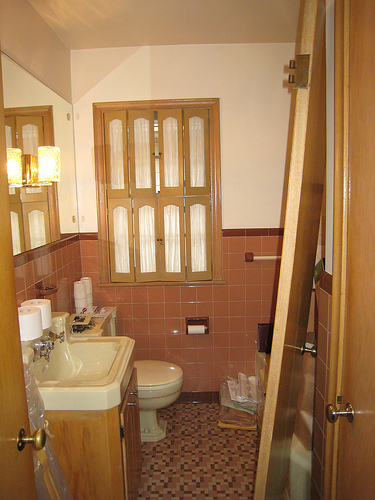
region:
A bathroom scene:
[7, 11, 361, 488]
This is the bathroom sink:
[21, 313, 137, 410]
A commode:
[132, 339, 192, 451]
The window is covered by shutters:
[95, 95, 224, 286]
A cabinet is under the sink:
[113, 364, 147, 498]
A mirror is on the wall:
[0, 45, 79, 258]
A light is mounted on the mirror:
[22, 140, 64, 194]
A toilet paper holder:
[183, 309, 218, 340]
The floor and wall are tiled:
[185, 352, 217, 440]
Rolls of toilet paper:
[17, 295, 57, 340]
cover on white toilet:
[134, 349, 198, 412]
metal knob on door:
[322, 388, 360, 429]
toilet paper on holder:
[176, 318, 207, 342]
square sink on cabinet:
[68, 331, 134, 419]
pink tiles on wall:
[214, 286, 247, 334]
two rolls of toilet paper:
[13, 293, 58, 346]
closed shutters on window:
[101, 191, 221, 290]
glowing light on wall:
[28, 138, 68, 194]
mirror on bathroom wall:
[25, 88, 81, 261]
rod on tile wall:
[235, 250, 274, 267]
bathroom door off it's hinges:
[251, 3, 325, 498]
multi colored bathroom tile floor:
[141, 402, 261, 497]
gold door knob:
[16, 424, 48, 458]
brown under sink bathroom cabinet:
[29, 364, 136, 498]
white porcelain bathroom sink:
[21, 310, 138, 410]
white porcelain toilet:
[76, 303, 184, 442]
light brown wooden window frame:
[91, 101, 223, 285]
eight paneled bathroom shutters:
[101, 102, 214, 282]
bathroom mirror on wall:
[0, 97, 82, 257]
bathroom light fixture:
[6, 145, 60, 190]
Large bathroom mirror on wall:
[0, 50, 78, 255]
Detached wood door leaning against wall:
[253, 0, 336, 499]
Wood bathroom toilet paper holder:
[184, 314, 210, 339]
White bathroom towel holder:
[241, 250, 288, 264]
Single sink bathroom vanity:
[23, 310, 142, 499]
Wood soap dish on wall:
[33, 279, 58, 298]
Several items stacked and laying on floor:
[216, 371, 260, 431]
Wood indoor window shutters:
[102, 108, 211, 282]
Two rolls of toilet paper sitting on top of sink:
[18, 297, 54, 341]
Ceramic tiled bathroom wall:
[228, 266, 270, 320]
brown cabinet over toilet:
[97, 112, 229, 276]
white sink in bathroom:
[7, 328, 139, 399]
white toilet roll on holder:
[185, 315, 208, 339]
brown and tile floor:
[169, 401, 227, 489]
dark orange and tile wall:
[86, 235, 223, 374]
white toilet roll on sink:
[18, 290, 54, 337]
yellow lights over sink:
[10, 128, 54, 181]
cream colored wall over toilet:
[178, 60, 271, 121]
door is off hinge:
[233, 59, 318, 445]